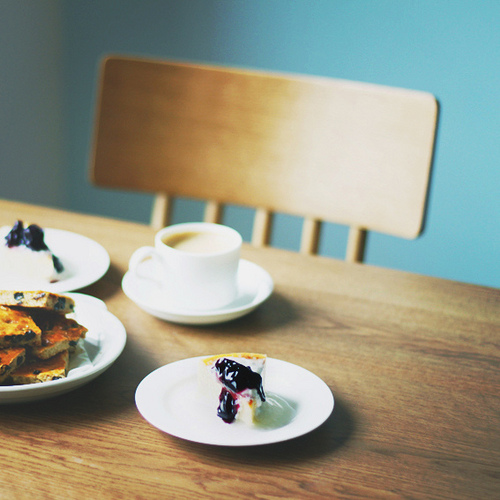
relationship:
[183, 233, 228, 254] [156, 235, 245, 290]
coffee in cup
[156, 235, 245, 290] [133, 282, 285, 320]
cup on saucer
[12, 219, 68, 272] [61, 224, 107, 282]
dessert on saucer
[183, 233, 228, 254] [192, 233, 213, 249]
coffee has creamer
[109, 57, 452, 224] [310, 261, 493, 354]
chair by table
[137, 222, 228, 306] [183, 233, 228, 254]
mug has coffee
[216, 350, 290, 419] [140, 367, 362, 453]
food on plate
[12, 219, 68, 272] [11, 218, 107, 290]
dessert on plate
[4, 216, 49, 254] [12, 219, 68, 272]
blackberries on dessert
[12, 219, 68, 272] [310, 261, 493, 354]
dessert on table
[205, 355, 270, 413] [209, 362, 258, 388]
cheesecake has toppings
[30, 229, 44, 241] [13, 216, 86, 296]
sauce on pie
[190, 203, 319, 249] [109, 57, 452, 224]
slats in chair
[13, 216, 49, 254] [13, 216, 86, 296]
blackberries on pie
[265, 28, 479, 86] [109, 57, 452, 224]
wall behind chair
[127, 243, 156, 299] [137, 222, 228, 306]
handle on mug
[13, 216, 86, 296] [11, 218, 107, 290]
pie on plate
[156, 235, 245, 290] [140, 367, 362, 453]
cup by plate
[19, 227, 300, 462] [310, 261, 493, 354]
plates on table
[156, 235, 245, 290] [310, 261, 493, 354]
cup on table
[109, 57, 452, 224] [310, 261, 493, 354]
chair at table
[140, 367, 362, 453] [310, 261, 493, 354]
plate on table